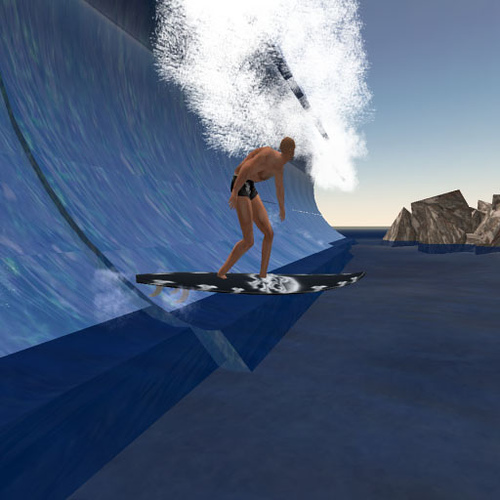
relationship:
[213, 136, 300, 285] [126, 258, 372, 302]
man standing on surfboard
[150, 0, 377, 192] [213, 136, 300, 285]
wave about to splash on man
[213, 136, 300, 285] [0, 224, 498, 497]
man surfing on water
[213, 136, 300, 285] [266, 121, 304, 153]
man with hair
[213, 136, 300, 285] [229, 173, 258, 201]
man wearing swim trunks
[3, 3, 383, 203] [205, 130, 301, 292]
wave bigger than man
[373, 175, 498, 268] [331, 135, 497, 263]
large rocks in background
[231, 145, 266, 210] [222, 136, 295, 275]
arm of a man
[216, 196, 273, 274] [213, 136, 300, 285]
legs of a man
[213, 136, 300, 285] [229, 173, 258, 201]
man wearing a swim trunks